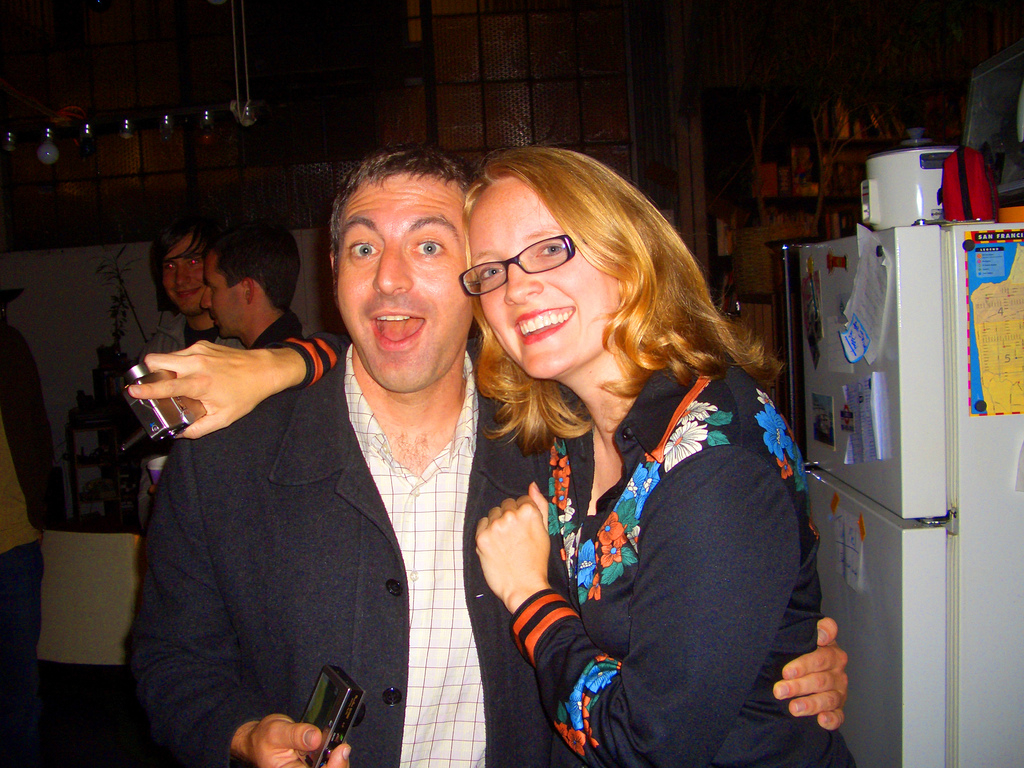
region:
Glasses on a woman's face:
[452, 231, 574, 295]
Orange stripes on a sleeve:
[509, 584, 574, 651]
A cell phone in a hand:
[307, 673, 365, 762]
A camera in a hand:
[125, 350, 214, 446]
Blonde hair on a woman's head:
[466, 151, 781, 408]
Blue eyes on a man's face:
[342, 234, 444, 257]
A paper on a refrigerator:
[962, 220, 1019, 411]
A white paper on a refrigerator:
[822, 489, 870, 597]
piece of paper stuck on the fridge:
[844, 223, 884, 354]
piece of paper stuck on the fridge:
[959, 236, 1014, 411]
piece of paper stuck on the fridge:
[842, 368, 882, 457]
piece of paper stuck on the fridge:
[833, 504, 866, 588]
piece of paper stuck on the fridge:
[825, 378, 852, 467]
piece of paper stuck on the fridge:
[807, 390, 833, 452]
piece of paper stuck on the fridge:
[817, 245, 850, 277]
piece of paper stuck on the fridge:
[798, 273, 822, 322]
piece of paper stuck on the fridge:
[804, 315, 827, 369]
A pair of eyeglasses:
[449, 217, 583, 309]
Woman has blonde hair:
[449, 130, 803, 460]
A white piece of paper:
[822, 209, 902, 374]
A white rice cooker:
[844, 111, 968, 235]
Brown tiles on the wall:
[2, 1, 651, 257]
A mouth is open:
[358, 294, 435, 358]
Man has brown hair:
[188, 206, 307, 346]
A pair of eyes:
[337, 226, 452, 275]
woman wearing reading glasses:
[451, 234, 581, 293]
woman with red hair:
[452, 141, 785, 427]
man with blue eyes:
[329, 224, 450, 269]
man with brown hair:
[328, 154, 477, 227]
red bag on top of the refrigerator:
[932, 141, 993, 218]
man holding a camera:
[259, 642, 371, 751]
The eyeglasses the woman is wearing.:
[447, 227, 593, 297]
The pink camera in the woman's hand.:
[113, 369, 213, 443]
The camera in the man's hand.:
[299, 657, 364, 766]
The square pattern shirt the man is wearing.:
[347, 363, 490, 763]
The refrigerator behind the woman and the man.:
[782, 228, 1023, 763]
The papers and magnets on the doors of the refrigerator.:
[791, 223, 905, 610]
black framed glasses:
[452, 231, 579, 301]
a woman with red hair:
[461, 138, 851, 767]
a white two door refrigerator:
[776, 221, 1023, 766]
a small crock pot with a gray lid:
[856, 124, 962, 227]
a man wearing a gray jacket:
[125, 142, 552, 762]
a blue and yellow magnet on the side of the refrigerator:
[955, 224, 1020, 418]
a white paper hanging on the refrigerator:
[840, 369, 894, 469]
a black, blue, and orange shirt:
[514, 367, 854, 766]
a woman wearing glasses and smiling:
[461, 149, 844, 761]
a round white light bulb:
[34, 135, 67, 170]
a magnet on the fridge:
[909, 231, 1018, 340]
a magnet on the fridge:
[846, 344, 882, 406]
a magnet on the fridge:
[846, 524, 886, 556]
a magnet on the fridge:
[817, 253, 894, 333]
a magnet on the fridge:
[802, 256, 821, 333]